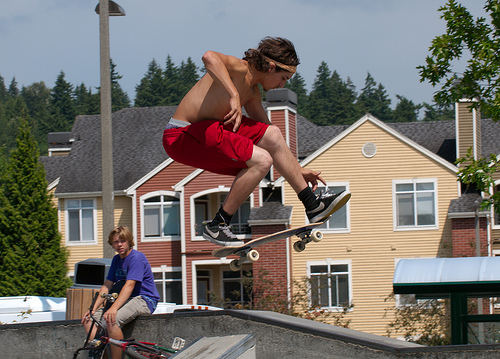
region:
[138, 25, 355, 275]
a boy skateboarding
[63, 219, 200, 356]
a boy sitting on a skateboard ramp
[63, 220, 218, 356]
a boy with a bicycle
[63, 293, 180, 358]
a red and black bicycle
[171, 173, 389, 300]
white and black nike sneakers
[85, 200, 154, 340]
a boy wearing a tshirt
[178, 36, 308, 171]
a boy wearing no shirt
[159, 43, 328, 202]
a boy wearing red shorts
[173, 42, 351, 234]
a boy wearing black and white nike shoes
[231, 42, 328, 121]
a boy with brown hair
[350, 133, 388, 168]
small white attic window surrounded by aluminum siding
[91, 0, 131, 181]
tall metal lamppost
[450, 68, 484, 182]
house chimney partially covered by a tree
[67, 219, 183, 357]
boy sitting down with his bike in front of him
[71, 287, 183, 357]
boy's freestyle bicycle laying on its side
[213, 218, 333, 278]
skateboard in the air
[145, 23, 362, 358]
skateboarder with no shirt on high above the ground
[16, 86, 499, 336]
condominium attached housing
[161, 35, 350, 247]
boy wearing a headband and no shirt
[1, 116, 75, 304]
tall and symmetrical pine tree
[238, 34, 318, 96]
boy has brown hair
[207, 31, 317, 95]
boy has orange headband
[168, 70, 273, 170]
boy has red shorts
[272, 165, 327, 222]
boy has black socks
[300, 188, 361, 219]
black and white shoes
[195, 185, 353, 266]
boy is on skateboard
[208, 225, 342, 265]
white wheels on board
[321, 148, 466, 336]
peach siding on house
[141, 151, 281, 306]
red brick siding on house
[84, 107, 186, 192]
houses have grey roofs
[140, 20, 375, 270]
Young man is skateboarding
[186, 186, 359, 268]
Man is wearing black shoes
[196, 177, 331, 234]
Man is wearing black socks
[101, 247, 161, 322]
Young kid is wearing a purple shirt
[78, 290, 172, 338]
Young kid is wearing shorts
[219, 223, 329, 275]
Skateboard wheels are tan in color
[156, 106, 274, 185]
Young man is wearing red shorts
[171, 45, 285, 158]
Young man is shirtless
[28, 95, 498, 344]
Houses in the background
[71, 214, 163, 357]
Young kid is sitting down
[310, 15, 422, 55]
cloudy with no sign of rain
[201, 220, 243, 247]
nike shoe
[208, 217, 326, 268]
skateboard in mid air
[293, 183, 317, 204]
black tube socks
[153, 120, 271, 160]
red shorts with pockets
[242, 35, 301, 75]
hair with headband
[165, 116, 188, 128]
boxers used as underwear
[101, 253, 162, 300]
purple shirt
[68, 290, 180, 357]
turned over bicycle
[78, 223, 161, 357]
kid sitting on ledge